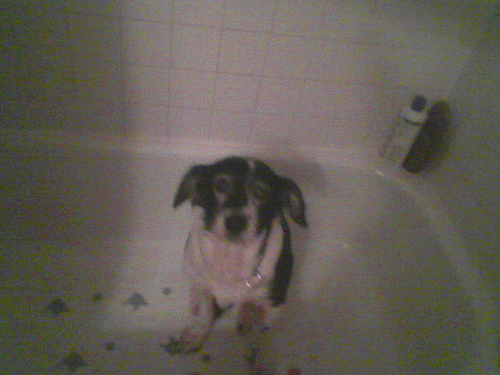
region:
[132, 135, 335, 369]
the dog is in the bathtub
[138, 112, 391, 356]
the dog is white and black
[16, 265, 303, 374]
a grippy pattern on the tub floor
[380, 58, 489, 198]
shampoo and soap bottles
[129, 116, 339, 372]
a dog in a bathtub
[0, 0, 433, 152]
the tiled wall in a bathtub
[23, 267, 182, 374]
the stickers on the bathtub floor are shaped like fish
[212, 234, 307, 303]
part of the dog's collar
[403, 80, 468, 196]
a black soap bottle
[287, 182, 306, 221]
an ear on the dog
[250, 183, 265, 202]
an eye on the dog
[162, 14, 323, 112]
part of the tiled wall in bathroom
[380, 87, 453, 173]
two bottles on ledge of bathtub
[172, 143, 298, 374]
a black and white dog in tub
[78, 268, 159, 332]
several decals on bottom of tub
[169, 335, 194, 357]
a paw on the dog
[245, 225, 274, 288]
part of collar around dog's neck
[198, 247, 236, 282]
white fur on the dog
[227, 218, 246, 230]
the snout on the dog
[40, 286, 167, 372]
stickers in the bottom of the tub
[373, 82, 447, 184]
bottles in the corner of the tub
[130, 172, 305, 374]
dog sitting in the tub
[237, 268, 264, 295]
loop on the dog's collar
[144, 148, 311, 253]
dog's ears are down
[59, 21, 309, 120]
tile wall of bathroom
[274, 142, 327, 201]
shadow of the dog on the tub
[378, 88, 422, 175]
blue and white bottle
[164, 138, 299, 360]
dog is about to get a bath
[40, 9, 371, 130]
white tile on the wall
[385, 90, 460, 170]
a bottle of shampoo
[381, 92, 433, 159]
a bottle of conditioner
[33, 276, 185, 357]
the floor of the tub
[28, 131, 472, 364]
a white bath tub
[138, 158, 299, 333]
a dog sitting in a bath tub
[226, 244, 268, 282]
the collar on the dog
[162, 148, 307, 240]
the face of the dog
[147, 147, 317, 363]
a black and white dog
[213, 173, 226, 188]
the eye of the dog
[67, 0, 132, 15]
plain white bathroom tile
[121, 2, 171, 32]
plain white bathroom tile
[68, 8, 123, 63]
plain white bathroom tile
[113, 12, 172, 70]
plain white bathroom tile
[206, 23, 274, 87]
plain white bathroom tile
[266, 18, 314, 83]
plain white bathroom tile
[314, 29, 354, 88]
plain white bathroom tile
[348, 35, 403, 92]
plain white bathroom tile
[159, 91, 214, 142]
plain white bathroom tile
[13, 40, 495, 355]
a dog looking at camera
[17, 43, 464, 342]
a dog in a bathtub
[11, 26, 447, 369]
a dog that appears to be neglected by its owner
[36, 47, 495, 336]
a scene in a bathroom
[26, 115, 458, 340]
a with tub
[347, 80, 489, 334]
a couple of soap bottles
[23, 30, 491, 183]
a white tiled wall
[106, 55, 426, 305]
a scene inside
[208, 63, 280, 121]
a white tile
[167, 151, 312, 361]
The dog in the tub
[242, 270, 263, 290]
The ring on the collar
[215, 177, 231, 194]
the eye of the dog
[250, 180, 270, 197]
the eye of the dog